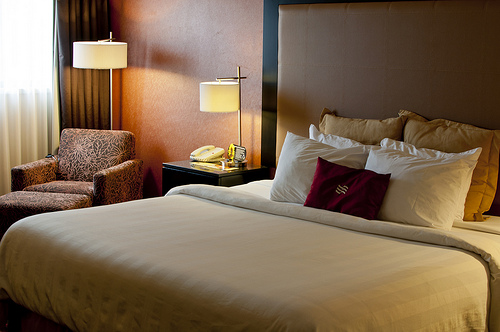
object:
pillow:
[365, 146, 483, 232]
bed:
[0, 180, 499, 332]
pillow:
[302, 156, 392, 220]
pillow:
[267, 123, 482, 232]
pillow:
[379, 137, 483, 222]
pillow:
[268, 131, 369, 205]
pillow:
[397, 109, 500, 222]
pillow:
[268, 107, 498, 231]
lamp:
[199, 82, 239, 113]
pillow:
[269, 130, 478, 232]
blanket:
[0, 184, 500, 331]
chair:
[9, 128, 143, 214]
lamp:
[73, 41, 128, 70]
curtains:
[0, 0, 60, 190]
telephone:
[190, 145, 226, 162]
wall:
[118, 0, 261, 188]